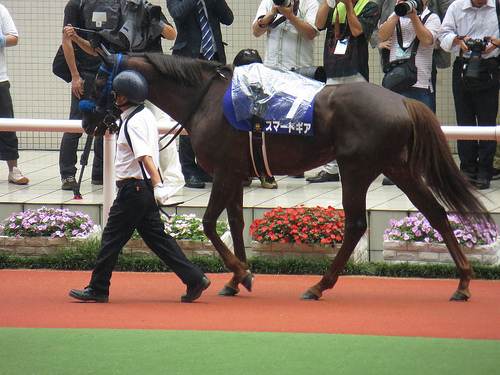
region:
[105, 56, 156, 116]
Man's helmet is black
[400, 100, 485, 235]
Horse's tail is brown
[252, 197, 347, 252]
Red flowers in background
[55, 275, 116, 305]
Man's left foot has shoe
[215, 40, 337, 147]
Horse's saddle is blue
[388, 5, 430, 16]
Camera of photographer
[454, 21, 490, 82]
Camera pointed down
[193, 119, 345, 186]
Horse's belly is brown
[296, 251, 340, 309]
Horse's back left hoof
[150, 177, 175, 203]
Wearing white glove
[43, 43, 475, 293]
a tall brown horse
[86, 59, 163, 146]
man wearing a helmet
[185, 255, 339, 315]
horses hooves are black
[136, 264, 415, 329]
the ground is orange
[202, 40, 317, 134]
the saddle is taped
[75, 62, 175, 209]
man wearing a white shirt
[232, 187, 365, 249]
a bushel of red flowers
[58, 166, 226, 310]
man wearing black pants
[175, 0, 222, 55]
a blue and white tie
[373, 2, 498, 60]
people taking pictures of the horse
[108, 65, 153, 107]
dark blue head gear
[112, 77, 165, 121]
dark blue head gear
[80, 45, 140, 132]
horse with blue harness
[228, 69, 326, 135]
blue saddle on horse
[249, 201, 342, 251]
red flowers in a planter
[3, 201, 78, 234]
pink flowers in a planter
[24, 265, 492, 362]
green and red floor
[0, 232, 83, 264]
white brick planter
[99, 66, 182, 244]
man wearing white shirt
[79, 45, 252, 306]
man walking with a horse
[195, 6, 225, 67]
blue and white tie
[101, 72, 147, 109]
man wearing black helmet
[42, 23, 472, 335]
a brown large horse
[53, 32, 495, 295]
a brown horse walking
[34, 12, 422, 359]
a horse is walking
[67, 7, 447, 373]
a man guiding a horse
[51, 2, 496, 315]
a man guiding a large horse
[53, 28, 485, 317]
a horse with a saddle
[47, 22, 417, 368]
a horse for show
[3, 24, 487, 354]
a brown show horse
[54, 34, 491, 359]
a show horse walking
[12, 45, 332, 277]
a man wearing a helmet